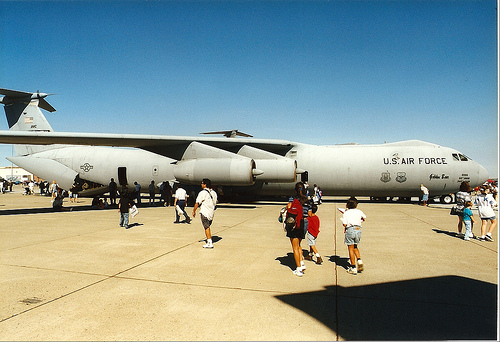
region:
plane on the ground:
[25, 108, 486, 222]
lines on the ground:
[88, 248, 163, 307]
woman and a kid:
[252, 165, 332, 273]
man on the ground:
[173, 165, 236, 230]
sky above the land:
[111, 59, 196, 116]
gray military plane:
[20, 111, 461, 193]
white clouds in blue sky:
[42, 16, 93, 47]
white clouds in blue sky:
[196, 41, 236, 73]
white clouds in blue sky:
[366, 39, 431, 89]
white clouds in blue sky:
[186, 46, 247, 80]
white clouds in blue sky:
[309, 71, 343, 91]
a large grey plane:
[0, 78, 489, 205]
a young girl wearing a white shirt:
[339, 209, 365, 229]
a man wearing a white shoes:
[203, 236, 215, 251]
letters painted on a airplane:
[379, 154, 451, 168]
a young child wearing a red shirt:
[304, 212, 324, 237]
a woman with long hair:
[296, 180, 308, 200]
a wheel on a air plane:
[440, 190, 457, 205]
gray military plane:
[14, 93, 489, 193]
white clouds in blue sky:
[371, 38, 419, 85]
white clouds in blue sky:
[170, 52, 202, 83]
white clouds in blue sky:
[51, 16, 93, 56]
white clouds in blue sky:
[292, 19, 324, 40]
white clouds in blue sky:
[134, 31, 169, 65]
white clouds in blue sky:
[214, 42, 268, 77]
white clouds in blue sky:
[374, 106, 405, 126]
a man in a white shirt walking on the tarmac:
[193, 178, 220, 250]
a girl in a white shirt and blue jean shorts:
[341, 194, 368, 276]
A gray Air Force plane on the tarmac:
[0, 91, 492, 201]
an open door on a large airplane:
[117, 165, 127, 192]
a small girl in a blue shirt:
[461, 199, 476, 239]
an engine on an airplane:
[174, 141, 261, 185]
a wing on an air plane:
[0, 133, 307, 147]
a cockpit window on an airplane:
[453, 151, 460, 161]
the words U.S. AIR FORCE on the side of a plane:
[384, 157, 451, 165]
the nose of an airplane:
[476, 162, 489, 187]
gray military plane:
[2, 82, 490, 189]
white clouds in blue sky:
[84, 37, 99, 58]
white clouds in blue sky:
[362, 24, 398, 49]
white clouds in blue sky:
[290, 66, 323, 108]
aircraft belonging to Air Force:
[1, 79, 494, 202]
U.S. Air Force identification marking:
[382, 155, 451, 166]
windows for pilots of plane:
[451, 151, 470, 162]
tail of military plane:
[0, 83, 66, 156]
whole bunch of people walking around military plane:
[5, 168, 497, 280]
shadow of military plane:
[2, 195, 448, 219]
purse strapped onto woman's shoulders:
[449, 197, 464, 216]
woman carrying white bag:
[115, 184, 141, 231]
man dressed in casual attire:
[190, 179, 222, 249]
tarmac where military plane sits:
[0, 172, 498, 340]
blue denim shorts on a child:
[347, 229, 362, 249]